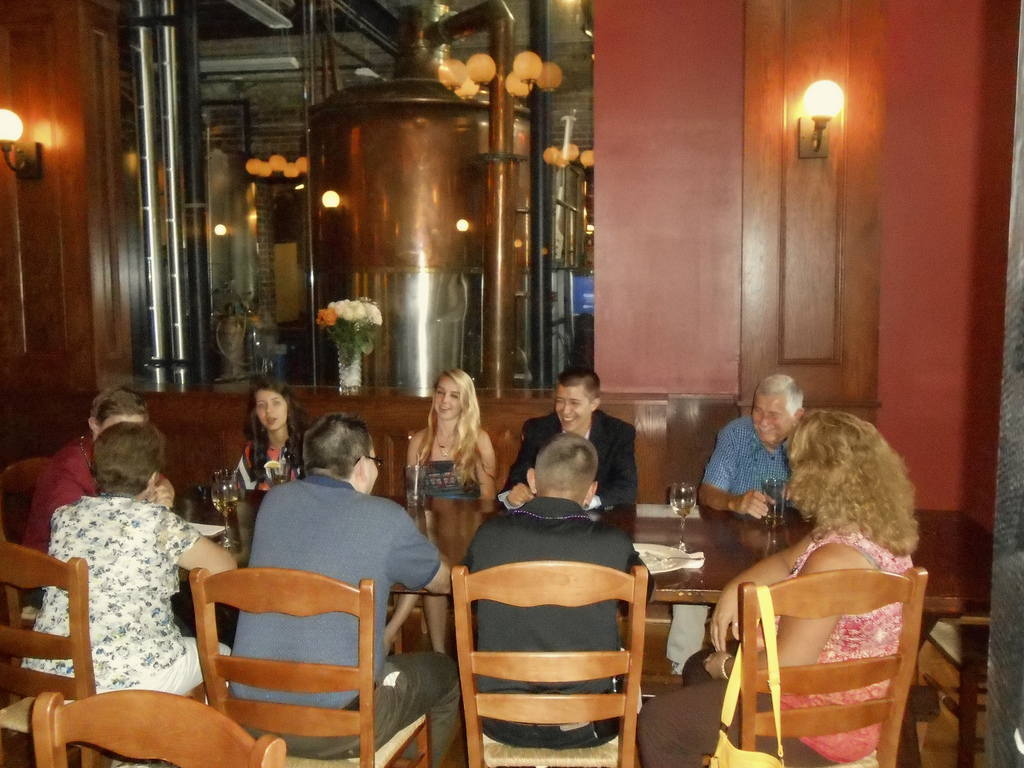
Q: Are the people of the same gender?
A: Yes, all the people are female.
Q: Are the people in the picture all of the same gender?
A: Yes, all the people are female.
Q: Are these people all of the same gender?
A: Yes, all the people are female.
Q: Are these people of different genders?
A: No, all the people are female.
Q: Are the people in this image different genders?
A: No, all the people are female.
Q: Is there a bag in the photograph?
A: Yes, there is a bag.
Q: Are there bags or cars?
A: Yes, there is a bag.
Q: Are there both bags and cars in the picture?
A: No, there is a bag but no cars.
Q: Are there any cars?
A: No, there are no cars.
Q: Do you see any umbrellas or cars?
A: No, there are no cars or umbrellas.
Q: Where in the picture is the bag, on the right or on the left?
A: The bag is on the right of the image.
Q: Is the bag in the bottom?
A: Yes, the bag is in the bottom of the image.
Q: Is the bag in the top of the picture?
A: No, the bag is in the bottom of the image.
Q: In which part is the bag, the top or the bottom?
A: The bag is in the bottom of the image.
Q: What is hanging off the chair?
A: The bag is hanging off the chair.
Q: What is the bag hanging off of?
A: The bag is hanging off the chair.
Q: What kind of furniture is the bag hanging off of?
A: The bag is hanging off the chair.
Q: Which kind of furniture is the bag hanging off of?
A: The bag is hanging off the chair.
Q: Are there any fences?
A: No, there are no fences.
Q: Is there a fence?
A: No, there are no fences.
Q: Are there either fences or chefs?
A: No, there are no fences or chefs.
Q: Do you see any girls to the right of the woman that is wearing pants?
A: Yes, there is a girl to the right of the woman.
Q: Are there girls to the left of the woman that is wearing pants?
A: No, the girl is to the right of the woman.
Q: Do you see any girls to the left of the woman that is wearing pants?
A: No, the girl is to the right of the woman.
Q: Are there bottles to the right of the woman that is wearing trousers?
A: No, there is a girl to the right of the woman.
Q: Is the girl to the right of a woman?
A: Yes, the girl is to the right of a woman.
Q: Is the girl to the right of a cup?
A: No, the girl is to the right of a woman.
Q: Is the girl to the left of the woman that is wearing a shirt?
A: No, the girl is to the right of the woman.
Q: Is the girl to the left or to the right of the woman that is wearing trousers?
A: The girl is to the right of the woman.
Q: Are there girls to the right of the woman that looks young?
A: Yes, there is a girl to the right of the woman.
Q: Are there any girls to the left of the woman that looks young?
A: No, the girl is to the right of the woman.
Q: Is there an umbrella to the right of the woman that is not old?
A: No, there is a girl to the right of the woman.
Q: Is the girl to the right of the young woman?
A: Yes, the girl is to the right of the woman.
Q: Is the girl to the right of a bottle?
A: No, the girl is to the right of the woman.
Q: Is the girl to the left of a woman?
A: No, the girl is to the right of a woman.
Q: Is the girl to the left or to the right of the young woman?
A: The girl is to the right of the woman.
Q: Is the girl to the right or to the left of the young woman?
A: The girl is to the right of the woman.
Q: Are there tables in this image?
A: Yes, there is a table.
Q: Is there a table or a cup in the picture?
A: Yes, there is a table.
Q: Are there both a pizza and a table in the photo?
A: No, there is a table but no pizzas.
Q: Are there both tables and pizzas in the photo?
A: No, there is a table but no pizzas.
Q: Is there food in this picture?
A: No, there is no food.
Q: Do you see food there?
A: No, there is no food.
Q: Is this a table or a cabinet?
A: This is a table.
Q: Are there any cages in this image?
A: No, there are no cages.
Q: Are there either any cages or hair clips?
A: No, there are no cages or hair clips.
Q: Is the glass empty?
A: Yes, the glass is empty.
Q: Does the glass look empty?
A: Yes, the glass is empty.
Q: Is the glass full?
A: No, the glass is empty.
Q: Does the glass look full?
A: No, the glass is empty.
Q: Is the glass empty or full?
A: The glass is empty.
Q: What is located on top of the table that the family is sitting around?
A: The glass is on top of the table.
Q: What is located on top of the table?
A: The glass is on top of the table.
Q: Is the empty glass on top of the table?
A: Yes, the glass is on top of the table.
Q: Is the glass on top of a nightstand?
A: No, the glass is on top of the table.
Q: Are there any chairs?
A: Yes, there is a chair.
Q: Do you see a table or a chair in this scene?
A: Yes, there is a chair.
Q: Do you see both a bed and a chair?
A: No, there is a chair but no beds.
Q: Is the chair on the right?
A: Yes, the chair is on the right of the image.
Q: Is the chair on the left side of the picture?
A: No, the chair is on the right of the image.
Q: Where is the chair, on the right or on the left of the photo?
A: The chair is on the right of the image.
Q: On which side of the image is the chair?
A: The chair is on the right of the image.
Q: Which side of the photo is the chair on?
A: The chair is on the right of the image.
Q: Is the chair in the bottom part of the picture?
A: Yes, the chair is in the bottom of the image.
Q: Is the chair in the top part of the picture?
A: No, the chair is in the bottom of the image.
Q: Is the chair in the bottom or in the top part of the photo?
A: The chair is in the bottom of the image.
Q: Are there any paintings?
A: No, there are no paintings.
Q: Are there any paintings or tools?
A: No, there are no paintings or tools.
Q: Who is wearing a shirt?
A: The family is wearing a shirt.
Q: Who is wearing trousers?
A: The family is wearing trousers.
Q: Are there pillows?
A: No, there are no pillows.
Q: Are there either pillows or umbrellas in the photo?
A: No, there are no pillows or umbrellas.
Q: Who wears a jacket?
A: The family wears a jacket.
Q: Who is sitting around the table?
A: The family is sitting around the table.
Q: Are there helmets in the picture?
A: No, there are no helmets.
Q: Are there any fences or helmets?
A: No, there are no helmets or fences.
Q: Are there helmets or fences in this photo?
A: No, there are no helmets or fences.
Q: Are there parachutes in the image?
A: No, there are no parachutes.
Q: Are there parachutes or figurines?
A: No, there are no parachutes or figurines.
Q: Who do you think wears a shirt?
A: The family wears a shirt.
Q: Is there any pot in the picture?
A: No, there are no pots.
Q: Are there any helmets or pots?
A: No, there are no pots or helmets.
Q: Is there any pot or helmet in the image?
A: No, there are no pots or helmets.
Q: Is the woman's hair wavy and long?
A: Yes, the hair is wavy and long.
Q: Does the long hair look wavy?
A: Yes, the hair is wavy.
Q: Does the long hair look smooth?
A: No, the hair is wavy.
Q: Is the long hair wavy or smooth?
A: The hair is wavy.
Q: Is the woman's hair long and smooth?
A: No, the hair is long but wavy.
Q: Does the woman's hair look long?
A: Yes, the hair is long.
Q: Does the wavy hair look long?
A: Yes, the hair is long.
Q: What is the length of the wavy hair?
A: The hair is long.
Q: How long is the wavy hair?
A: The hair is long.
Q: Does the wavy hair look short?
A: No, the hair is long.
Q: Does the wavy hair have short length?
A: No, the hair is long.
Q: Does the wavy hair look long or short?
A: The hair is long.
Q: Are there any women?
A: Yes, there is a woman.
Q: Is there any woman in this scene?
A: Yes, there is a woman.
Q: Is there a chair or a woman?
A: Yes, there is a woman.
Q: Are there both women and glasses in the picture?
A: Yes, there are both a woman and glasses.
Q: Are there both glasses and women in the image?
A: Yes, there are both a woman and glasses.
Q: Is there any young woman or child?
A: Yes, there is a young woman.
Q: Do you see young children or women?
A: Yes, there is a young woman.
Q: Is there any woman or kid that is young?
A: Yes, the woman is young.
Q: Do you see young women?
A: Yes, there is a young woman.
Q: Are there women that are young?
A: Yes, there is a woman that is young.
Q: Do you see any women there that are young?
A: Yes, there is a woman that is young.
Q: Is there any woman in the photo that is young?
A: Yes, there is a woman that is young.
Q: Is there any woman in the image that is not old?
A: Yes, there is an young woman.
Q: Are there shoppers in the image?
A: No, there are no shoppers.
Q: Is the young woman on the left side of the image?
A: Yes, the woman is on the left of the image.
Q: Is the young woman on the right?
A: No, the woman is on the left of the image.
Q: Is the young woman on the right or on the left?
A: The woman is on the left of the image.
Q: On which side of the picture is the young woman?
A: The woman is on the left of the image.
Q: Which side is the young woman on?
A: The woman is on the left of the image.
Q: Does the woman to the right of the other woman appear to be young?
A: Yes, the woman is young.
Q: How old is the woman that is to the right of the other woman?
A: The woman is young.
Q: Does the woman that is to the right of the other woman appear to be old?
A: No, the woman is young.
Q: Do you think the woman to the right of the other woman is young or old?
A: The woman is young.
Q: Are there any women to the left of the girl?
A: Yes, there is a woman to the left of the girl.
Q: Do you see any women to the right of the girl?
A: No, the woman is to the left of the girl.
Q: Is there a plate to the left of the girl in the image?
A: No, there is a woman to the left of the girl.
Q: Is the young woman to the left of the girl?
A: Yes, the woman is to the left of the girl.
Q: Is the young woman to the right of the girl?
A: No, the woman is to the left of the girl.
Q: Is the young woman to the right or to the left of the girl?
A: The woman is to the left of the girl.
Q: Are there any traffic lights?
A: No, there are no traffic lights.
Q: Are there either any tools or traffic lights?
A: No, there are no traffic lights or tools.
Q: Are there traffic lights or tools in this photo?
A: No, there are no traffic lights or tools.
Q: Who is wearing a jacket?
A: The family is wearing a jacket.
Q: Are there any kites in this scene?
A: No, there are no kites.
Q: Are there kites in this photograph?
A: No, there are no kites.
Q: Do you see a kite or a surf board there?
A: No, there are no kites or surfboards.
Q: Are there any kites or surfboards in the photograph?
A: No, there are no kites or surfboards.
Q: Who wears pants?
A: The family wears pants.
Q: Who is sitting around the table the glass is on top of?
A: The family is sitting around the table.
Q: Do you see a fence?
A: No, there are no fences.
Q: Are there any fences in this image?
A: No, there are no fences.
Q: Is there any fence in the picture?
A: No, there are no fences.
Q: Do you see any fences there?
A: No, there are no fences.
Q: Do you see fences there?
A: No, there are no fences.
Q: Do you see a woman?
A: Yes, there is a woman.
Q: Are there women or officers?
A: Yes, there is a woman.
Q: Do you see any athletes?
A: No, there are no athletes.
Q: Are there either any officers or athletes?
A: No, there are no athletes or officers.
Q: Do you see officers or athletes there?
A: No, there are no athletes or officers.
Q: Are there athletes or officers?
A: No, there are no athletes or officers.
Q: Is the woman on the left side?
A: Yes, the woman is on the left of the image.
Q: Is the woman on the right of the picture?
A: No, the woman is on the left of the image.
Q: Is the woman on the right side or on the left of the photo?
A: The woman is on the left of the image.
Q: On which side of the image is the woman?
A: The woman is on the left of the image.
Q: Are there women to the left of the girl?
A: Yes, there is a woman to the left of the girl.